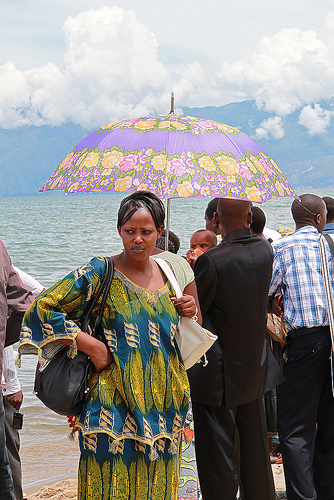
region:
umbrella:
[54, 104, 250, 197]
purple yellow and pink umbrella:
[58, 113, 246, 192]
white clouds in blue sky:
[15, 12, 48, 47]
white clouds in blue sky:
[7, 42, 42, 90]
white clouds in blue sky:
[9, 69, 60, 118]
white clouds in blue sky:
[59, 21, 133, 62]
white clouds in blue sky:
[250, 86, 313, 136]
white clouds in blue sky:
[151, 27, 209, 59]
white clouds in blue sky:
[207, 15, 254, 58]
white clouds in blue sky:
[129, 54, 207, 88]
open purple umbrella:
[64, 113, 263, 202]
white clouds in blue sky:
[11, 6, 62, 57]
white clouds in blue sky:
[49, 19, 106, 69]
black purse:
[28, 339, 92, 417]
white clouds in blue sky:
[183, 17, 233, 51]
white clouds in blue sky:
[220, 64, 272, 98]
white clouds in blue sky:
[247, 11, 302, 71]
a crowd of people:
[23, 157, 332, 322]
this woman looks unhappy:
[65, 176, 225, 390]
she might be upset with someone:
[85, 182, 207, 359]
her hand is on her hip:
[42, 260, 212, 368]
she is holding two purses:
[33, 244, 210, 411]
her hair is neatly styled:
[106, 184, 176, 266]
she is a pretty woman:
[86, 178, 176, 322]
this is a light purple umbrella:
[46, 90, 295, 203]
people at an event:
[185, 204, 281, 320]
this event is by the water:
[28, 216, 261, 344]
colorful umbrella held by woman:
[62, 108, 268, 199]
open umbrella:
[45, 117, 285, 203]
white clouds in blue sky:
[13, 87, 39, 118]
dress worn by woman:
[107, 306, 179, 462]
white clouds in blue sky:
[29, 41, 80, 79]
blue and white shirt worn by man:
[280, 226, 321, 319]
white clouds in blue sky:
[199, 36, 282, 123]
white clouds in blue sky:
[271, 49, 317, 103]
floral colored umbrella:
[80, 115, 246, 175]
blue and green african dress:
[42, 281, 203, 490]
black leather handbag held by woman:
[54, 273, 110, 411]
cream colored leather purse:
[160, 280, 220, 381]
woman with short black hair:
[115, 195, 162, 225]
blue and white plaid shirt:
[271, 209, 332, 304]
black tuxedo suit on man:
[204, 241, 270, 495]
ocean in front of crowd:
[33, 205, 100, 267]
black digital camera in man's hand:
[15, 406, 32, 438]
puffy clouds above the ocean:
[40, 51, 272, 129]